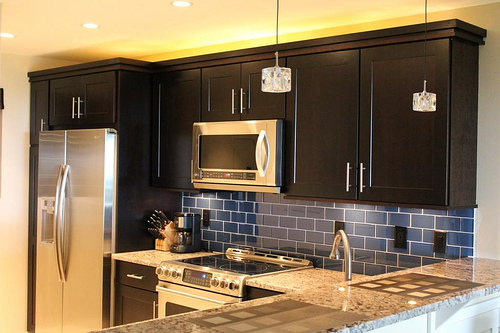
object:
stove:
[155, 247, 315, 298]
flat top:
[172, 253, 304, 275]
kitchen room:
[0, 0, 500, 331]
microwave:
[191, 119, 283, 193]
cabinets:
[202, 57, 285, 121]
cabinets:
[285, 37, 480, 210]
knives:
[156, 220, 165, 230]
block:
[154, 221, 177, 252]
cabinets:
[48, 69, 156, 129]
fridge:
[34, 128, 120, 332]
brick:
[271, 226, 287, 240]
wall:
[206, 199, 367, 242]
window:
[198, 134, 259, 170]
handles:
[346, 162, 352, 192]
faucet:
[329, 229, 352, 281]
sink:
[246, 268, 369, 291]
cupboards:
[153, 60, 200, 193]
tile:
[223, 221, 238, 234]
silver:
[157, 281, 240, 302]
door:
[157, 280, 242, 319]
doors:
[62, 128, 110, 333]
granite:
[290, 285, 423, 325]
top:
[294, 257, 500, 316]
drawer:
[115, 259, 157, 293]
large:
[0, 0, 499, 333]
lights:
[261, 67, 292, 94]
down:
[259, 50, 292, 93]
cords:
[275, 0, 280, 63]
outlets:
[394, 225, 408, 249]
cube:
[412, 92, 436, 112]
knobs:
[155, 267, 162, 275]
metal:
[328, 229, 352, 282]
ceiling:
[0, 0, 500, 56]